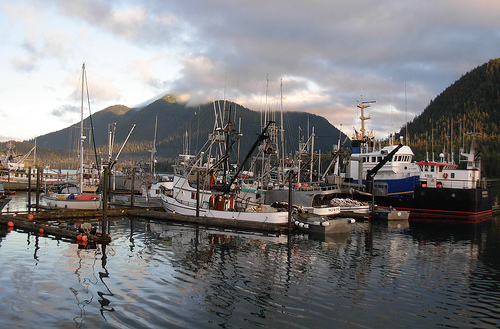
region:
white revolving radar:
[177, 152, 194, 160]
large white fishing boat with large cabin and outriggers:
[159, 86, 298, 224]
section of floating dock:
[9, 218, 112, 245]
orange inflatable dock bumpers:
[75, 233, 87, 240]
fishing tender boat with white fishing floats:
[292, 209, 353, 237]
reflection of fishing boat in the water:
[130, 217, 291, 257]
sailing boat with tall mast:
[43, 60, 106, 209]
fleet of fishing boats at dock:
[1, 1, 499, 324]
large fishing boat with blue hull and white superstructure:
[336, 101, 420, 199]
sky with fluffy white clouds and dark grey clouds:
[3, 2, 499, 130]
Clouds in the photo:
[267, 30, 377, 82]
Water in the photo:
[141, 264, 288, 307]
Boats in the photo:
[43, 162, 298, 243]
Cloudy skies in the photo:
[199, 12, 369, 93]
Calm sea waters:
[127, 244, 245, 311]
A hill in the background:
[102, 88, 325, 148]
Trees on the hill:
[412, 80, 489, 131]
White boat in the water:
[155, 164, 295, 236]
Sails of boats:
[204, 102, 273, 168]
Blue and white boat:
[354, 132, 424, 195]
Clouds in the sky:
[218, 12, 355, 81]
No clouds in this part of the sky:
[10, 76, 44, 120]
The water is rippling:
[88, 263, 353, 320]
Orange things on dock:
[74, 231, 90, 246]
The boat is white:
[150, 176, 291, 226]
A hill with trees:
[392, 59, 497, 157]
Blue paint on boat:
[372, 174, 419, 191]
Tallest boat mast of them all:
[79, 59, 85, 191]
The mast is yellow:
[353, 97, 369, 141]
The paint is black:
[415, 186, 492, 213]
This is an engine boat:
[166, 172, 298, 252]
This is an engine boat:
[283, 185, 403, 258]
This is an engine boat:
[23, 182, 127, 222]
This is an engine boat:
[6, 152, 88, 194]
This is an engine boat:
[84, 112, 162, 200]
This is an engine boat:
[150, 139, 182, 204]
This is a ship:
[345, 104, 426, 194]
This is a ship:
[398, 121, 495, 233]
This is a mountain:
[236, 75, 343, 172]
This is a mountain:
[188, 69, 262, 168]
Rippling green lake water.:
[60, 251, 383, 313]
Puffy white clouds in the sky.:
[41, 58, 152, 103]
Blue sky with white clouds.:
[22, 8, 172, 70]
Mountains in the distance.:
[63, 87, 332, 154]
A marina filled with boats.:
[11, 135, 487, 235]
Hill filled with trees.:
[395, 61, 488, 143]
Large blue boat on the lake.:
[334, 128, 419, 199]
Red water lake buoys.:
[0, 210, 112, 259]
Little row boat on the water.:
[373, 196, 418, 233]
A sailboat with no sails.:
[35, 44, 110, 209]